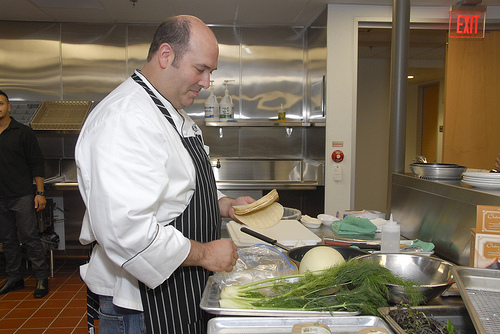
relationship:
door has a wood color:
[443, 33, 499, 172] [459, 55, 499, 118]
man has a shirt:
[73, 15, 284, 332] [72, 69, 221, 312]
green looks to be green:
[332, 271, 360, 281] [347, 271, 360, 277]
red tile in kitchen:
[6, 299, 83, 332] [0, 3, 498, 331]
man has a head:
[73, 15, 284, 332] [143, 11, 219, 110]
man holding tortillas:
[73, 15, 284, 332] [234, 186, 284, 230]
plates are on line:
[461, 163, 499, 189] [389, 154, 500, 266]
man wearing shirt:
[0, 91, 52, 299] [2, 117, 47, 202]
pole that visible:
[385, 0, 412, 223] [396, 11, 407, 161]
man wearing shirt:
[73, 15, 284, 332] [72, 69, 221, 312]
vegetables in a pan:
[402, 312, 456, 333] [378, 303, 493, 333]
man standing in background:
[0, 91, 52, 299] [1, 2, 497, 190]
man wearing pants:
[0, 91, 52, 299] [0, 194, 52, 279]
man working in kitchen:
[73, 15, 284, 332] [0, 3, 498, 331]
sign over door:
[449, 9, 489, 41] [443, 33, 499, 172]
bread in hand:
[241, 205, 284, 225] [231, 189, 258, 226]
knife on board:
[241, 226, 297, 253] [227, 218, 322, 249]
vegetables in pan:
[402, 312, 456, 333] [378, 303, 493, 333]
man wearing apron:
[73, 15, 284, 332] [131, 71, 221, 333]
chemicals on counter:
[203, 77, 289, 120] [200, 112, 330, 133]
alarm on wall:
[330, 140, 348, 181] [322, 2, 358, 220]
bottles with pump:
[203, 78, 236, 123] [207, 77, 235, 92]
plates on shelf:
[410, 160, 467, 181] [389, 154, 500, 266]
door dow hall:
[415, 87, 439, 165] [355, 32, 446, 222]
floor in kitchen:
[3, 249, 96, 333] [0, 3, 498, 331]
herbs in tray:
[252, 271, 390, 309] [200, 272, 381, 316]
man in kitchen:
[73, 15, 284, 332] [0, 3, 498, 331]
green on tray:
[347, 271, 360, 277] [200, 272, 381, 316]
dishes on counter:
[301, 208, 342, 228] [231, 218, 468, 334]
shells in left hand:
[234, 186, 284, 230] [231, 189, 258, 226]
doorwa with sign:
[356, 24, 499, 215] [449, 9, 489, 41]